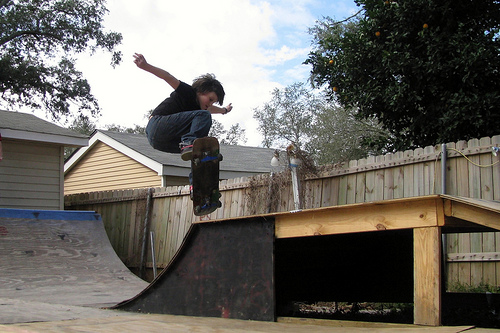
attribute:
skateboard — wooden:
[190, 137, 222, 215]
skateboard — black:
[182, 132, 228, 219]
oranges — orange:
[306, 0, 451, 84]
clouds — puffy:
[118, 14, 269, 77]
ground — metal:
[410, 110, 435, 139]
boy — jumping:
[137, 60, 214, 204]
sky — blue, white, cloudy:
[1, 0, 369, 152]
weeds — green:
[444, 267, 499, 311]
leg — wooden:
[407, 227, 439, 325]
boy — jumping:
[124, 46, 248, 237]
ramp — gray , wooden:
[0, 197, 500, 332]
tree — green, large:
[293, 1, 497, 135]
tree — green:
[0, 30, 130, 128]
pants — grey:
[138, 105, 227, 201]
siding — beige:
[65, 144, 189, 197]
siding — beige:
[3, 140, 63, 209]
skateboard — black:
[188, 138, 220, 215]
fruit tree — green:
[302, 0, 495, 137]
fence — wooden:
[104, 137, 496, 270]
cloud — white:
[130, 8, 258, 48]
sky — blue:
[224, 5, 319, 54]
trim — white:
[0, 127, 268, 179]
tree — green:
[0, 1, 124, 124]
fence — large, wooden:
[238, 134, 496, 202]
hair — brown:
[193, 73, 225, 107]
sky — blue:
[8, 6, 497, 139]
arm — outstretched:
[125, 45, 189, 90]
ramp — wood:
[2, 199, 247, 311]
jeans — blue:
[146, 107, 218, 153]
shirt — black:
[140, 76, 210, 118]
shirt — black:
[152, 82, 200, 115]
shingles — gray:
[5, 105, 307, 173]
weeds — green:
[274, 286, 498, 320]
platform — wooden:
[122, 187, 494, 328]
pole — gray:
[435, 137, 448, 194]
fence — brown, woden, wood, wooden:
[63, 131, 484, 295]